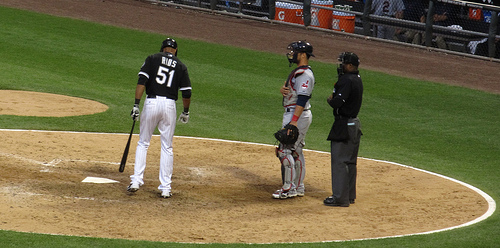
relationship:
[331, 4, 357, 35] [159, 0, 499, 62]
cooler behind fence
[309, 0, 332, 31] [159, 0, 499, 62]
cooler behind fence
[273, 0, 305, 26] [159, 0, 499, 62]
cooler behind fence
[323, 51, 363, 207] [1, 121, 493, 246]
baseball player on dirt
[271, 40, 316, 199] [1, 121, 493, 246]
baseball player on dirt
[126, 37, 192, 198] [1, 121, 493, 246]
baseball player on dirt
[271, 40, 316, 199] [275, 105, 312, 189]
baseball player wears pants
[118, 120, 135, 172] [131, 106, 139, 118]
baseball bat in hand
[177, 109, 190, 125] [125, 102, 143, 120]
batting glove on hand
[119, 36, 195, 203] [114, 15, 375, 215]
baseball player plays baseball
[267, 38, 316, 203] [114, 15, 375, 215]
baseball player plays baseball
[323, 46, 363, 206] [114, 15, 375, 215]
baseball player plays baseball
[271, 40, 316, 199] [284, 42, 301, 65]
baseball player wears mask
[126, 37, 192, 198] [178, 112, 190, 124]
baseball player wears batting glove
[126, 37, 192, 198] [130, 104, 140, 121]
baseball player wears batting glove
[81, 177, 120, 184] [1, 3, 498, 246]
base in baseball field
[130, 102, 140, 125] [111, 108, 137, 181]
hand hold baseball bat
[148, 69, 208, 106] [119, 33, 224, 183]
number on player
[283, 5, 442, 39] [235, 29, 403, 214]
fence behind players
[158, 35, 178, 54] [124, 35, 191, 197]
helmet on player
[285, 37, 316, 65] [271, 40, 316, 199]
helmet on baseball player